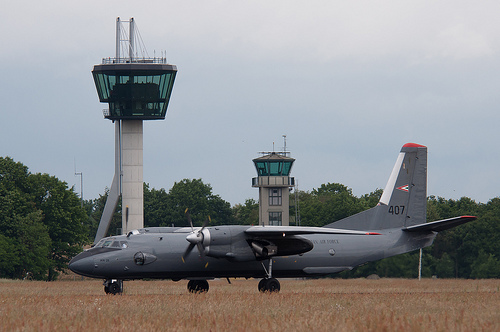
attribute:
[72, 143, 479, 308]
grey airplane — gray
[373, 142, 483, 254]
tail — plane, white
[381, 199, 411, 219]
numbers — black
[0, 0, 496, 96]
clouds — white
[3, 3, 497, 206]
sky — blue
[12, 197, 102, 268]
leaves — green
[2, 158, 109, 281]
trees — green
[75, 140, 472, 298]
airplane — gray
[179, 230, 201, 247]
propeller nose — silver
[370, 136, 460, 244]
tail — tip, red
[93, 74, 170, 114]
windows — Green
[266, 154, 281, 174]
windows — Green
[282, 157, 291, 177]
windows — Green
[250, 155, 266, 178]
windows — Green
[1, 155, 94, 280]
leaves — Green 